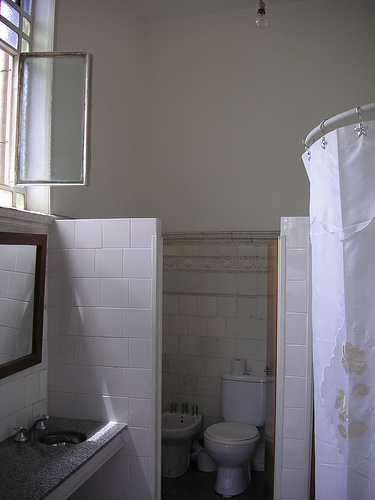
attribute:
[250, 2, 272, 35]
light — small, hanging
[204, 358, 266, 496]
toilet — small, white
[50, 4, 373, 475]
wall — white, long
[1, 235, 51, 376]
mirror — silver, above, close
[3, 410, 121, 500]
sink — grey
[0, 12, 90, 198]
window — white, open, glass, pane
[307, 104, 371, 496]
curtains — white